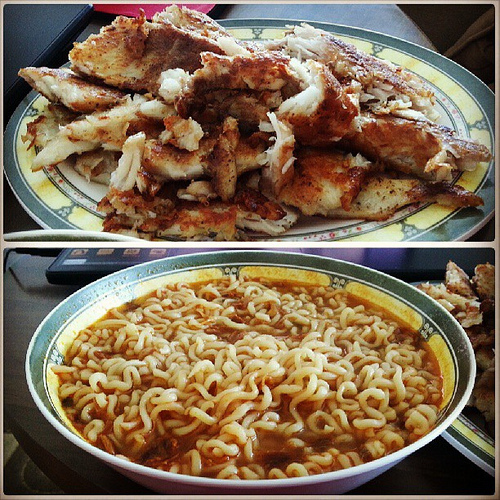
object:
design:
[53, 195, 78, 219]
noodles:
[352, 374, 396, 429]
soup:
[59, 276, 441, 480]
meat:
[261, 444, 290, 465]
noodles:
[126, 387, 165, 443]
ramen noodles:
[340, 306, 353, 329]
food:
[18, 5, 494, 241]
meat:
[413, 282, 484, 330]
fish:
[274, 59, 361, 146]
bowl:
[24, 248, 476, 488]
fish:
[67, 5, 225, 94]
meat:
[350, 111, 494, 185]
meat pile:
[17, 3, 494, 241]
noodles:
[218, 384, 272, 428]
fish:
[17, 64, 123, 113]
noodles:
[188, 363, 280, 425]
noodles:
[335, 339, 352, 355]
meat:
[109, 130, 146, 193]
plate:
[409, 280, 500, 478]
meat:
[260, 112, 295, 193]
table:
[0, 0, 493, 495]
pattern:
[50, 275, 442, 479]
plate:
[2, 16, 492, 253]